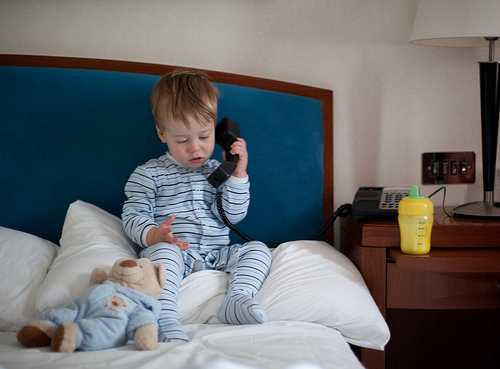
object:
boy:
[118, 69, 270, 342]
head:
[150, 70, 220, 168]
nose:
[185, 138, 201, 153]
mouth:
[186, 155, 206, 163]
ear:
[152, 123, 168, 144]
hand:
[220, 136, 249, 177]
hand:
[143, 214, 191, 251]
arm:
[119, 164, 155, 247]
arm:
[211, 166, 252, 226]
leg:
[211, 238, 270, 328]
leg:
[140, 241, 190, 347]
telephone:
[201, 115, 418, 252]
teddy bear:
[13, 257, 168, 354]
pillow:
[31, 197, 390, 352]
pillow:
[1, 222, 49, 328]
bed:
[1, 197, 390, 368]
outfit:
[120, 151, 274, 349]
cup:
[393, 183, 436, 255]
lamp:
[406, 0, 499, 219]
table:
[336, 200, 497, 368]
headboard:
[0, 57, 337, 252]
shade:
[408, 0, 496, 49]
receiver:
[206, 113, 243, 189]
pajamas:
[45, 277, 161, 351]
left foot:
[215, 292, 266, 325]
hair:
[148, 70, 221, 133]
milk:
[398, 225, 432, 256]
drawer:
[382, 246, 499, 313]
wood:
[393, 251, 498, 274]